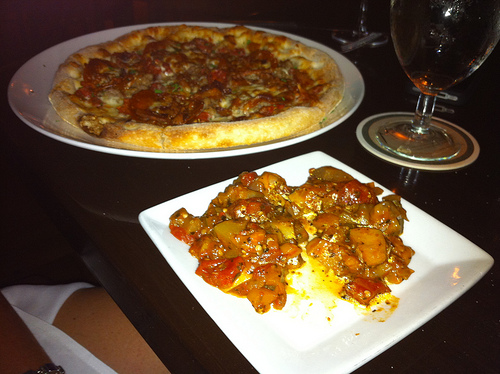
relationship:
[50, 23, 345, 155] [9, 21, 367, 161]
pizza on a plate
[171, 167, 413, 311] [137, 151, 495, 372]
food on plate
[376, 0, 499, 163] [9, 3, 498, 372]
glass on table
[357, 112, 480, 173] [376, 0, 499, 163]
coaster for glass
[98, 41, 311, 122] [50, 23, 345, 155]
sauce on pizza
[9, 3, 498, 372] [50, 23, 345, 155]
table with pizza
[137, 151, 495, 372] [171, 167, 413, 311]
plate of food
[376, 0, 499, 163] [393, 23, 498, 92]
glass of wine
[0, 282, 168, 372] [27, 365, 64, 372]
person wearing a wrist watch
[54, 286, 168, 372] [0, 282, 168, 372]
thigh of person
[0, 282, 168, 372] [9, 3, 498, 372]
person at table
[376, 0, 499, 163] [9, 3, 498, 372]
glass with wine on table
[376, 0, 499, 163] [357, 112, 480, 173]
glass on top of coaster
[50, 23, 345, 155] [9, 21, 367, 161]
pizza on top of plate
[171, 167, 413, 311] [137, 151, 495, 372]
food on top of plate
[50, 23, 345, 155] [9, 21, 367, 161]
pizza on plate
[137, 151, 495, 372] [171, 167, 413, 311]
plate filled with food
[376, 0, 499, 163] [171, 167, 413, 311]
glass next to food